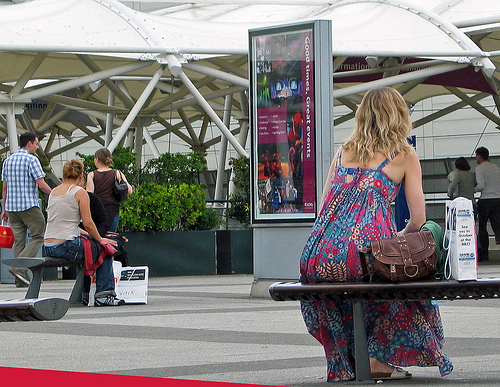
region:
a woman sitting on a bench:
[288, 88, 414, 279]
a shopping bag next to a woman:
[441, 187, 486, 289]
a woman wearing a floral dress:
[299, 91, 431, 356]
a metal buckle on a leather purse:
[404, 257, 420, 279]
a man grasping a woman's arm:
[456, 148, 498, 197]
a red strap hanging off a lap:
[84, 241, 102, 273]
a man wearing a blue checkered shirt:
[3, 126, 43, 252]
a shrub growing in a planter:
[124, 182, 215, 227]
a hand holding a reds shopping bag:
[0, 211, 16, 245]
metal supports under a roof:
[74, 65, 232, 137]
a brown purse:
[361, 227, 464, 304]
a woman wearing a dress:
[272, 77, 430, 384]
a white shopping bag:
[431, 177, 499, 297]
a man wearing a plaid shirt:
[0, 125, 75, 269]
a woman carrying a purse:
[61, 127, 152, 274]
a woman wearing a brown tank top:
[76, 147, 158, 258]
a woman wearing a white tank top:
[48, 142, 91, 270]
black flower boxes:
[117, 159, 282, 280]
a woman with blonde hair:
[306, 60, 453, 262]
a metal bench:
[261, 257, 496, 384]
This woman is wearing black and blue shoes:
[102, 295, 124, 317]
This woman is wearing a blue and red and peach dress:
[337, 147, 382, 344]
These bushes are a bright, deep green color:
[147, 196, 199, 223]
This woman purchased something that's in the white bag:
[448, 210, 480, 282]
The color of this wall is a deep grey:
[261, 236, 278, 277]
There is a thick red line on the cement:
[56, 370, 65, 384]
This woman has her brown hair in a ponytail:
[94, 150, 116, 180]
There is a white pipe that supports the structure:
[209, 128, 238, 152]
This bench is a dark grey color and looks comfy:
[4, 254, 18, 275]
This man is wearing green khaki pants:
[12, 202, 39, 236]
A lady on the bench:
[286, 61, 458, 320]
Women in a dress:
[277, 105, 428, 372]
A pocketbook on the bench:
[364, 185, 488, 333]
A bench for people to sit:
[44, 126, 155, 338]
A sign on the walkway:
[237, 15, 379, 242]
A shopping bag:
[431, 181, 483, 268]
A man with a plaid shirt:
[16, 129, 44, 236]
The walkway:
[159, 321, 263, 383]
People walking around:
[37, 112, 449, 300]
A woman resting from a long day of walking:
[316, 87, 444, 328]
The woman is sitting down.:
[308, 87, 463, 374]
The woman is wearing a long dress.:
[300, 136, 461, 385]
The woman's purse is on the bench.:
[366, 225, 450, 291]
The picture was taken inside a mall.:
[4, 3, 499, 384]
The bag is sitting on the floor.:
[111, 250, 158, 317]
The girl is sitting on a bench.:
[43, 157, 138, 319]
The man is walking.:
[0, 130, 54, 295]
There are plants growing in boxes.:
[113, 179, 225, 274]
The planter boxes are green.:
[115, 222, 222, 284]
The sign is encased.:
[240, 17, 331, 231]